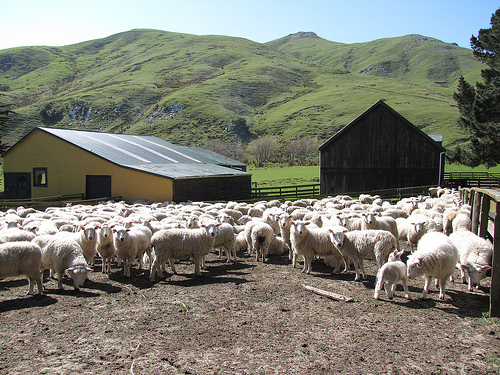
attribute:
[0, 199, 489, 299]
sheep — white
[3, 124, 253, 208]
building — yellow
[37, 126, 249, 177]
roof — dark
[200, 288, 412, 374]
ground — dirt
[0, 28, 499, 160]
hills — green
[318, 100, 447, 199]
house — small, wood, dark, wooden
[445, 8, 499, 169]
pine — green, tall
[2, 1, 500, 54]
sky — blue, clear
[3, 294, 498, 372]
dirt — brown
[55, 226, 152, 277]
sheep — white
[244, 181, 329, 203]
fence — between, wood, wooden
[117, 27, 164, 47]
grass — green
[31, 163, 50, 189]
window — square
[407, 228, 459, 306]
sheep — white, fluffy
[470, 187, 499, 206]
stick — wood